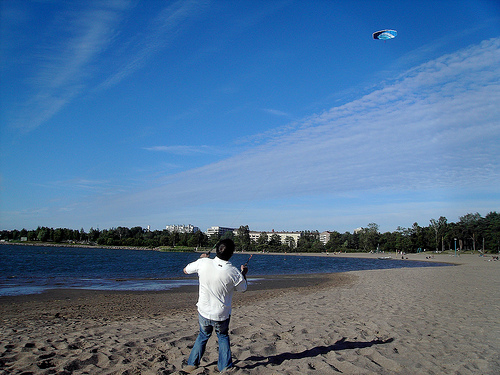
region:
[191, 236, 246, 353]
Person wearing white shirt.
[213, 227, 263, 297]
Person has dark hair.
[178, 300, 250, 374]
Person wearing blue jeans.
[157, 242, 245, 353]
Person standing in the sand.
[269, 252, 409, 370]
Sand is light brown in color.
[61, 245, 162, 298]
Water is blue in color.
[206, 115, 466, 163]
White clouds in the sky.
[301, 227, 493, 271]
Green trees near the sand.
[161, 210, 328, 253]
Large building beyond trees.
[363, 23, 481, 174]
Person is flying a kite.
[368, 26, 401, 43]
A kite high in the sky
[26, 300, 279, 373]
Heavily trampled sand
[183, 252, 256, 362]
A man wearing a white shirt and jeans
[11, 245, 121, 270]
Beautiful blue water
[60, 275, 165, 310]
Water coming up onto shore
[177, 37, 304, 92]
A bright blue sky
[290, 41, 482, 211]
White clouds in the sky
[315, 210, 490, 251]
Trees lining the shore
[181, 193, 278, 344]
A man flying a kite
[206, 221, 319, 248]
Buildings behind the trees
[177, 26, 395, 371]
man flying stunt kite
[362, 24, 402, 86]
blue stunt kite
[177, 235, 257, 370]
man in blue jeans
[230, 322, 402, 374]
shadow of man on the beach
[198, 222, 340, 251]
building behind the trees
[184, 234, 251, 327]
man in white polo shirt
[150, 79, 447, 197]
blue sky with clouds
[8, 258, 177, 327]
wet sand at the water's edge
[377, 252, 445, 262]
sunbathers at the beach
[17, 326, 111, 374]
footprints in beach sand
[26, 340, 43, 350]
a footstep in the sand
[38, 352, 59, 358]
a footstep in the sand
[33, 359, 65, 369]
a footstep in the sand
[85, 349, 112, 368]
a footstep in the sand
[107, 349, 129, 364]
a footstep in the sand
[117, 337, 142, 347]
a footstep in the sand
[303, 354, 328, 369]
a footstep in the sand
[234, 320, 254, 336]
a footstep in the sand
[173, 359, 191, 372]
a footstep in the sand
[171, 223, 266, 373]
a person flying a kite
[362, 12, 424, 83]
windsurfer sailing through the air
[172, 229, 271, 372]
man with a white shirt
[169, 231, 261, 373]
man in blue jeans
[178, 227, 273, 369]
man standing on the beach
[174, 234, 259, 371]
man watching a wind surfer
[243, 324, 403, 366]
shadow of a man on a beach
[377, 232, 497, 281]
people sun bathing on the beach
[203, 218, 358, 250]
large building on the water front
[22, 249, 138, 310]
sandy beach meets calm ocean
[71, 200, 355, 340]
man on a sunny beach